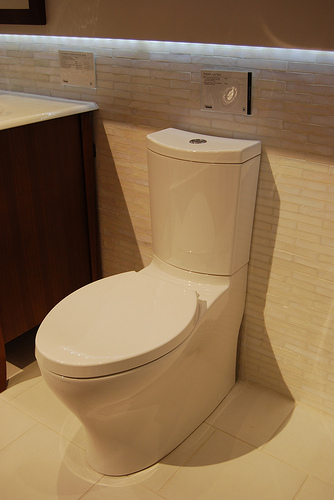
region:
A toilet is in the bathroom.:
[0, 0, 333, 499]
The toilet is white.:
[29, 126, 263, 480]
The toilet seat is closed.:
[30, 266, 202, 379]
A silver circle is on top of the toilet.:
[186, 135, 208, 146]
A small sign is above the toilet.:
[196, 64, 256, 116]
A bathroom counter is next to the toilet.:
[0, 88, 103, 396]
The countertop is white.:
[0, 84, 101, 134]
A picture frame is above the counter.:
[0, 1, 49, 26]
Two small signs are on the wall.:
[52, 43, 256, 118]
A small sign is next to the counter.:
[55, 46, 98, 88]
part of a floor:
[233, 404, 252, 437]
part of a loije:
[228, 442, 248, 485]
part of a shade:
[248, 400, 260, 427]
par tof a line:
[193, 439, 203, 456]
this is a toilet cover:
[24, 269, 166, 378]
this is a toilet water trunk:
[145, 128, 266, 276]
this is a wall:
[260, 56, 333, 389]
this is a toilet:
[35, 120, 272, 474]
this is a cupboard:
[4, 129, 117, 386]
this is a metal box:
[200, 71, 255, 120]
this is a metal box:
[52, 47, 102, 91]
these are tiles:
[0, 388, 332, 495]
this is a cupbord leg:
[0, 343, 6, 394]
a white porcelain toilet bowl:
[32, 255, 249, 475]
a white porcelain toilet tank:
[144, 127, 262, 277]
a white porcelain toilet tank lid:
[146, 127, 261, 163]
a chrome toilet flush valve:
[188, 137, 207, 144]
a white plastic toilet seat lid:
[33, 271, 199, 378]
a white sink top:
[0, 88, 99, 130]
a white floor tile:
[204, 379, 294, 449]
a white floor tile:
[262, 400, 333, 483]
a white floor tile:
[294, 475, 332, 497]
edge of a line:
[124, 341, 146, 362]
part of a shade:
[250, 408, 262, 427]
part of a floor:
[224, 386, 245, 435]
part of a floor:
[216, 417, 240, 469]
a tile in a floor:
[212, 376, 291, 444]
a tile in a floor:
[263, 403, 332, 485]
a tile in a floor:
[155, 427, 306, 498]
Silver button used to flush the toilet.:
[186, 136, 208, 147]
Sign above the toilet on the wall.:
[194, 67, 254, 115]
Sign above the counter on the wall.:
[54, 48, 100, 89]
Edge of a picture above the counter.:
[2, 1, 52, 25]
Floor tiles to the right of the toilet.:
[102, 384, 330, 497]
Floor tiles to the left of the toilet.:
[2, 361, 93, 497]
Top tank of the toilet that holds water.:
[142, 124, 252, 277]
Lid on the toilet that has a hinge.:
[34, 268, 198, 381]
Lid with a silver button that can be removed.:
[143, 125, 258, 164]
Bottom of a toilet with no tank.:
[32, 264, 260, 475]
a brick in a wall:
[239, 54, 287, 72]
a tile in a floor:
[76, 470, 163, 498]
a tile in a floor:
[2, 422, 102, 498]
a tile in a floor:
[1, 396, 36, 448]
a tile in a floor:
[13, 378, 89, 451]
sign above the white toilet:
[178, 52, 278, 129]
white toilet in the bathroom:
[29, 121, 261, 464]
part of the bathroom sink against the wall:
[4, 78, 127, 285]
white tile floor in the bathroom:
[224, 412, 319, 495]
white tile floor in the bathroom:
[10, 426, 86, 487]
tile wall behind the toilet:
[258, 301, 304, 379]